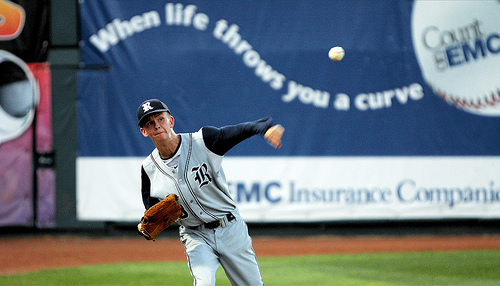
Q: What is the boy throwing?
A: Ball.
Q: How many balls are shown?
A: One.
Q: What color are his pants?
A: White.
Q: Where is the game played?
A: Field.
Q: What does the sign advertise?
A: Insurance.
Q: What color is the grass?
A: Green.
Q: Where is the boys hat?
A: Head.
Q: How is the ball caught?
A: Glove.